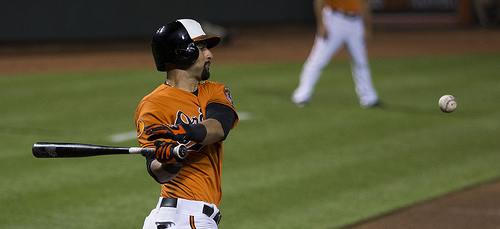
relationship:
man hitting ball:
[135, 19, 236, 228] [437, 93, 461, 115]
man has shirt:
[135, 19, 236, 228] [138, 81, 237, 205]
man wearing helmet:
[135, 19, 236, 228] [151, 19, 222, 70]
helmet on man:
[151, 19, 222, 70] [135, 19, 236, 228]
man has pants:
[135, 19, 236, 228] [143, 194, 222, 227]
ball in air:
[437, 93, 461, 115] [294, 39, 500, 206]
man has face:
[135, 19, 236, 228] [189, 41, 215, 84]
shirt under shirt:
[138, 81, 237, 205] [138, 81, 237, 205]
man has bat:
[135, 19, 236, 228] [33, 139, 189, 161]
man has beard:
[135, 19, 236, 228] [200, 60, 210, 80]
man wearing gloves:
[135, 19, 236, 228] [149, 122, 195, 164]